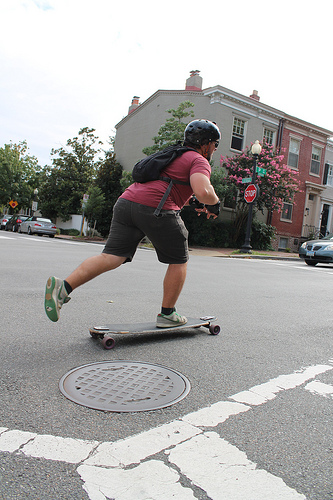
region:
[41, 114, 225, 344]
the man in the middle of the road skateboarding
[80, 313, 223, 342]
the skateboard under the man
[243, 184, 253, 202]
the STOP sign at the corner or the road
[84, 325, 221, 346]
the wheels on the skateboard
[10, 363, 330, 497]
the white lines on the road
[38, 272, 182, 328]
the shoes on the skateboarder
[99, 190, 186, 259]
the dark colored shorts on the skateboarder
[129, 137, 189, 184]
the backpack on the skateboarder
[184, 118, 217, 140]
the black helmet on the skateboarder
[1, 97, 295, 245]
the trees along the sidewalk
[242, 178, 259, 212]
Stop sign on a light pole.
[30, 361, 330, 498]
White lines on the ground.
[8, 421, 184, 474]
Cracks in the lines.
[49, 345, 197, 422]
Manhole on the ground.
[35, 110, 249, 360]
Man on a skateboard.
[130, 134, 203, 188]
Man has a backpack.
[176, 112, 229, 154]
Man is wearing a helmet.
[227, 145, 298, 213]
Flowers on the tree.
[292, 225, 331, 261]
Car at the stop sign.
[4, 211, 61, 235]
Cars on the side of the road.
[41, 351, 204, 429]
A metal manhole cover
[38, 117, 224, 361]
A person skateboarding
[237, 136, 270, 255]
A metal lamp post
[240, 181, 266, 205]
A red stop sign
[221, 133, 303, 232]
A pink flowering tree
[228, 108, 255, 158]
An open window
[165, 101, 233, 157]
A person wearing a black helmet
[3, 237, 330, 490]
A street intersection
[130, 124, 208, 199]
A small black backpack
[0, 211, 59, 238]
Three cars parked by the curb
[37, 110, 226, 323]
man skateboarding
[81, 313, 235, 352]
skateboard the man is riding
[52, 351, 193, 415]
manhole cover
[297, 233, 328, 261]
front end of car driving down the road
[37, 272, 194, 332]
shoes of skateboarder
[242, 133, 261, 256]
street light with white bulb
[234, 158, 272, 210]
stop sign and green street signs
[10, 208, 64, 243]
car parked up the street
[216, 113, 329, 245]
windows of the building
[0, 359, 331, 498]
white lines on the roadway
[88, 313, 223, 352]
A WOODEN SKATEBOARD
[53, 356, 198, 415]
A METAL MAN HOLE COVER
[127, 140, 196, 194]
A BLACK BACKPACK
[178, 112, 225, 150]
A BLACK HELMET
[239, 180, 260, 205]
A RED AND WHITE STOP SIGN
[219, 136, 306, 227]
A TREE WITH PINK FLOWERS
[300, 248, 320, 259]
A LICENSE PLATE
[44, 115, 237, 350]
A MAN ON A SKATEBOARD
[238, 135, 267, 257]
A TALL STREET LAMP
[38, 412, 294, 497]
WHITE MARKINGS ON THE PAVEMENT